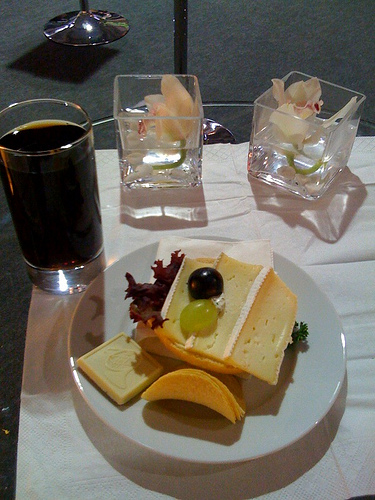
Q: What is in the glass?
A: A white orchid.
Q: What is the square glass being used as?
A: A vase.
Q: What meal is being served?
A: Lunch.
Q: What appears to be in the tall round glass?
A: Soda.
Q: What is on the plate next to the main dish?
A: Pringle chips.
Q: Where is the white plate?
A: On a table.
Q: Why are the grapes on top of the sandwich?
A: As a garnish.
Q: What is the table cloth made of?
A: Paper.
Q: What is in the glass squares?
A: Flowers.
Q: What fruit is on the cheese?
A: Grapes.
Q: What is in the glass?
A: Soda.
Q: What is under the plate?
A: A napkin.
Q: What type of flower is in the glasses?
A: Lillies.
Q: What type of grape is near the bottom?
A: Green grape.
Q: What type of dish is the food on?
A: A glass dish.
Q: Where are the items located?
A: On a table.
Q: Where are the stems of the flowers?
A: In the water.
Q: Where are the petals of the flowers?
A: Near the sides of the glasses.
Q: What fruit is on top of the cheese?
A: Grapes.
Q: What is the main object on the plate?
A: Cheese.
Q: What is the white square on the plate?
A: White chocolate.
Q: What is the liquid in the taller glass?
A: Soda.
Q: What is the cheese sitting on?
A: A plate.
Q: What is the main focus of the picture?
A: Food and drinks.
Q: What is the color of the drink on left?
A: Brown.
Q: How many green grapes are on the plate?
A: One.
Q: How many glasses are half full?
A: Two.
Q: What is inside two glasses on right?
A: Flower.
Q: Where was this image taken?
A: On a dining table.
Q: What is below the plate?
A: Paper napkin.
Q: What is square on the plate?
A: White chocolate.